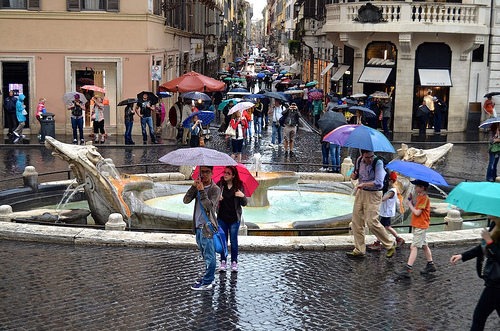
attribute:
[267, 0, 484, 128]
stone — white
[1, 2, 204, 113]
stone — peach colored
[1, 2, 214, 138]
peach — beige, tan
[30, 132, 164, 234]
cement — grey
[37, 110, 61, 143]
trash — grey